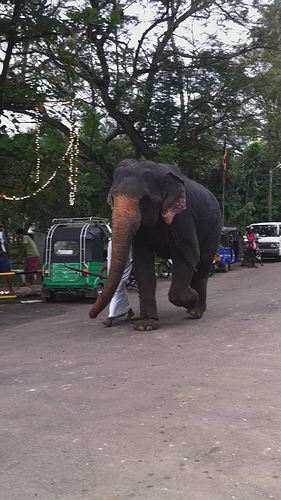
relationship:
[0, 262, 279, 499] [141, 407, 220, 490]
road has spots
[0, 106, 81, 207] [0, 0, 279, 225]
lights are in trees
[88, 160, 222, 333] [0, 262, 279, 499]
elephant on road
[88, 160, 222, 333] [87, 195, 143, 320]
elephant has trunk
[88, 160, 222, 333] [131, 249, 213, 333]
elephant has legs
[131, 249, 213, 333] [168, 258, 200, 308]
legs on front left high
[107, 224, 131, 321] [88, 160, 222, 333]
person near elephant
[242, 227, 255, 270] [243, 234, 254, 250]
person in red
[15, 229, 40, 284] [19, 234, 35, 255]
person in green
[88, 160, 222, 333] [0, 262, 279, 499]
elephant walking on road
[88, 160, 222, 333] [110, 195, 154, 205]
elephant has eyes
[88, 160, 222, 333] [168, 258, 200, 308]
elephant leg raised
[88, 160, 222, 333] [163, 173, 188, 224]
elephant has ear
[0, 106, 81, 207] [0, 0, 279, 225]
lights in trees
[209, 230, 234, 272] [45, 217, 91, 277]
vehicle has railing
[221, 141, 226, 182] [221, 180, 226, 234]
flag on pole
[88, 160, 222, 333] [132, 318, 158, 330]
elephant has foot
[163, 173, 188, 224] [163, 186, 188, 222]
ear has pink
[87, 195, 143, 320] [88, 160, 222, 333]
trunk on elephant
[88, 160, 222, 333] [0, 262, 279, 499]
elephant in road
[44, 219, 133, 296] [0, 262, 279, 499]
cars on road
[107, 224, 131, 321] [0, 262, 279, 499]
person in road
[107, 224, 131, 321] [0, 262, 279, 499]
person on road